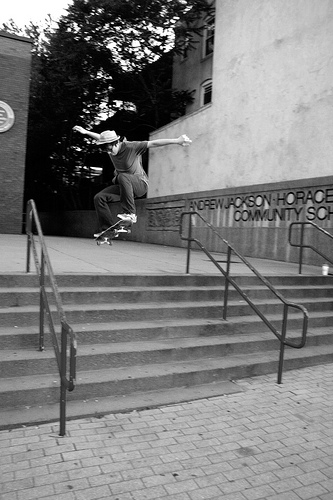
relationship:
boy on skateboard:
[71, 125, 192, 246] [91, 212, 147, 243]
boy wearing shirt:
[71, 125, 192, 246] [109, 137, 148, 189]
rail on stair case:
[174, 209, 308, 385] [8, 256, 331, 422]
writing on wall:
[190, 187, 332, 224] [147, 2, 330, 265]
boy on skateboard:
[68, 121, 190, 221] [92, 217, 127, 247]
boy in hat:
[71, 125, 192, 246] [88, 128, 123, 145]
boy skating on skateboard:
[71, 125, 192, 246] [88, 212, 138, 251]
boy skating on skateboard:
[71, 125, 192, 246] [92, 214, 133, 246]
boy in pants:
[71, 125, 192, 246] [92, 172, 151, 239]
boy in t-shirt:
[71, 125, 192, 246] [98, 133, 151, 182]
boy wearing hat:
[71, 125, 192, 246] [94, 130, 119, 145]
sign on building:
[1, 94, 16, 139] [1, 31, 36, 236]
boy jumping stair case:
[71, 125, 192, 246] [0, 274, 333, 431]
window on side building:
[196, 78, 218, 105] [141, 1, 329, 192]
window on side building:
[199, 10, 215, 57] [141, 1, 329, 192]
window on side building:
[179, 31, 191, 57] [141, 1, 329, 192]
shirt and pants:
[104, 147, 155, 177] [89, 175, 148, 224]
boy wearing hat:
[71, 125, 192, 246] [90, 126, 128, 149]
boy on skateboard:
[71, 125, 192, 246] [92, 214, 135, 253]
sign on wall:
[187, 185, 332, 230] [102, 174, 331, 272]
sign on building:
[187, 185, 332, 230] [148, 0, 330, 224]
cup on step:
[320, 262, 329, 277] [241, 265, 332, 286]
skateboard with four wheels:
[90, 217, 132, 246] [112, 230, 131, 237]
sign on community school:
[187, 185, 332, 230] [4, 0, 331, 434]